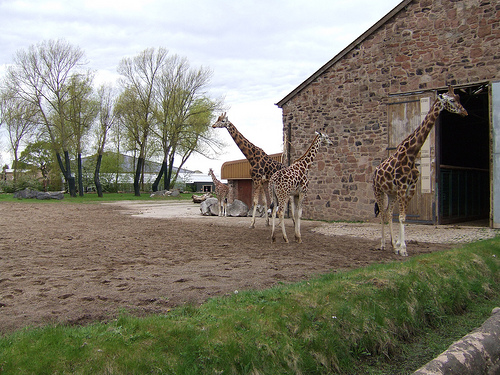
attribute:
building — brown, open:
[277, 4, 499, 221]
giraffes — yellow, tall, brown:
[193, 84, 463, 269]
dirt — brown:
[4, 202, 476, 330]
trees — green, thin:
[3, 43, 221, 205]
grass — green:
[9, 185, 138, 201]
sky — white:
[4, 2, 379, 140]